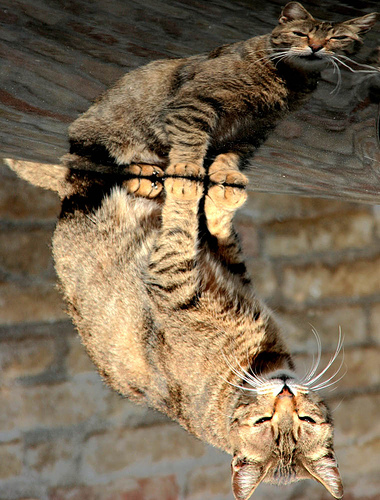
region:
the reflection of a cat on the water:
[0, 2, 379, 190]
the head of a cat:
[227, 369, 348, 497]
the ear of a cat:
[227, 453, 267, 497]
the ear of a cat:
[305, 462, 352, 498]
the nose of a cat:
[274, 382, 294, 398]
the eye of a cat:
[249, 411, 272, 427]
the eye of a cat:
[296, 412, 317, 429]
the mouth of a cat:
[268, 372, 300, 383]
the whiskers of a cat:
[216, 348, 266, 395]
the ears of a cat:
[229, 453, 346, 499]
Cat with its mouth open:
[74, 2, 374, 212]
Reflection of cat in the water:
[17, 143, 376, 498]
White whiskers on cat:
[243, 35, 378, 98]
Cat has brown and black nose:
[308, 35, 327, 53]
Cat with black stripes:
[137, 63, 229, 191]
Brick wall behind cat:
[4, 169, 378, 499]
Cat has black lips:
[299, 45, 327, 69]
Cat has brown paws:
[123, 153, 257, 187]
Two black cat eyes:
[290, 21, 349, 45]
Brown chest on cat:
[218, 50, 295, 138]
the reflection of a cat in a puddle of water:
[61, 0, 379, 181]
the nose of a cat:
[272, 386, 300, 418]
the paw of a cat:
[162, 176, 206, 204]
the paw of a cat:
[208, 183, 254, 220]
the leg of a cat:
[157, 180, 203, 285]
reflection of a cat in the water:
[67, 2, 379, 182]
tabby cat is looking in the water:
[6, 157, 345, 499]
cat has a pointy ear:
[230, 458, 271, 498]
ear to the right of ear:
[305, 454, 344, 497]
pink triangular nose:
[277, 386, 293, 397]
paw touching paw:
[164, 178, 203, 202]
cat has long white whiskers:
[212, 339, 269, 392]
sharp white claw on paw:
[150, 183, 155, 188]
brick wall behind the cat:
[0, 191, 379, 497]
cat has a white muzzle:
[255, 368, 310, 398]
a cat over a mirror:
[52, 2, 375, 184]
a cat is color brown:
[59, 1, 376, 179]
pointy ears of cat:
[273, 2, 378, 25]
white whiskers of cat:
[245, 44, 375, 91]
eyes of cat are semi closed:
[288, 22, 350, 44]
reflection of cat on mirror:
[16, 162, 362, 492]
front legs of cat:
[154, 174, 255, 290]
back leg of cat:
[108, 171, 156, 203]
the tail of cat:
[2, 158, 69, 198]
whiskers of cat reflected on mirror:
[208, 318, 354, 401]